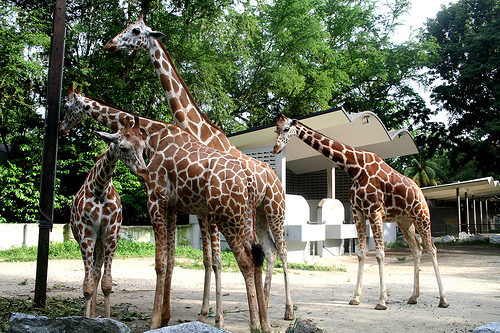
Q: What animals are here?
A: Giraffes.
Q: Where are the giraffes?
A: In the zoo.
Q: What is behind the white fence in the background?
A: Trees.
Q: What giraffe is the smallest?
A: The one on the left.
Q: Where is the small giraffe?
A: Next to big giraffe.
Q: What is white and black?
A: Roof of shelter.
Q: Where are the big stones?
A: In front of giraffe.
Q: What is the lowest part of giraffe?
A: Legs.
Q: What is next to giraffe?
A: Pole.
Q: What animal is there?
A: Giraffe.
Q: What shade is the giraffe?
A: Brown.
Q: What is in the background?
A: Trees.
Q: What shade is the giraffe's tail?
A: Black.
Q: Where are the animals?
A: Zoo.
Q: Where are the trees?
A: Back of pen.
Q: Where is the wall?
A: Behind giraffes.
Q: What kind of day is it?
A: Sunny.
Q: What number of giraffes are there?
A: Four.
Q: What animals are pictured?
A: Giraffes.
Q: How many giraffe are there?
A: Four.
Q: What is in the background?
A: Trees.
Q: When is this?
A: Daytime.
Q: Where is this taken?
A: The zoo.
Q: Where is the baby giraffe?
A: To the left of the other giraffe.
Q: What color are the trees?
A: Green.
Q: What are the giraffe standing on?
A: The dirt.